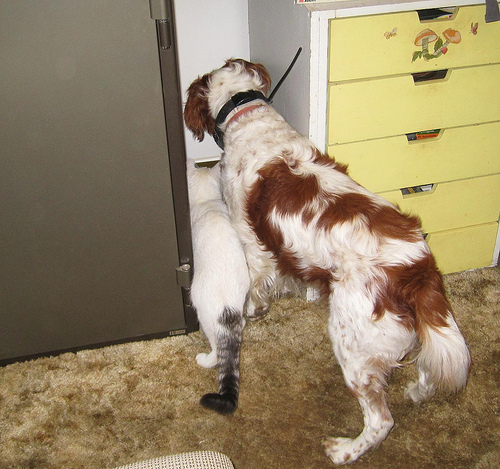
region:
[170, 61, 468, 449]
a dog and cat playing together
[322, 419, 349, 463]
The paw of a medium sized dog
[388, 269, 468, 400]
The tail of a medium sized dog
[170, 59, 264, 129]
The head of a medium sized dog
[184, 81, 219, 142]
The ear of a medium sized dog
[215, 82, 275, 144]
The neck of a medium sized dog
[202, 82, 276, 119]
The collar of a medium sized dog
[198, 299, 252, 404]
The tail of a small cat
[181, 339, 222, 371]
The paw of a small cat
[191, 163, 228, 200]
The head of a small cat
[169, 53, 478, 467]
og and cat standing in front of opening in the wall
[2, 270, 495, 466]
tan and brown carpet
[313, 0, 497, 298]
yellow drawers in chest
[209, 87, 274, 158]
black collar on neck of dog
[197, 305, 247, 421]
brown and black tail of cat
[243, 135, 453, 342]
brown patches of fur on back of white dog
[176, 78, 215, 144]
floppy brown dog ear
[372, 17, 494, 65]
mushrooms and butterfly designs on front of yellow chest of drawers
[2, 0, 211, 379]
grey door on room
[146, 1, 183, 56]
bottom of door hinge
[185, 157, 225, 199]
Head of small white cat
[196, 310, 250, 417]
Tail of white cat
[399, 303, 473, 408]
Tail of searching dog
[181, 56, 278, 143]
Head of curious dog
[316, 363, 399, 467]
Leg of curious dog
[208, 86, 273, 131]
Collar of curious dog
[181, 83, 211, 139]
Ear of curious dog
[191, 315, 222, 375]
Leg of white cat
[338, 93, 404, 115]
Part of yellow drawer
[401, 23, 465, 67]
Mushroom decoration on drawer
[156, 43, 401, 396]
a cat and a dog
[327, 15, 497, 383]
the drawers are yellow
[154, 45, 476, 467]
dog and cat on carpet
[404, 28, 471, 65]
decal on yellow drawer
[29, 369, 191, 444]
brown shag carpet on ground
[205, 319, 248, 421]
tail of a cat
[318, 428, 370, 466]
back paw of a cat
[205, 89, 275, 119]
collar on a dog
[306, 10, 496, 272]
yellow drawers in a cabinet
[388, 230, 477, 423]
tail of a dog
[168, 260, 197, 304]
hinge on a door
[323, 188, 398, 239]
brown spots on dogs